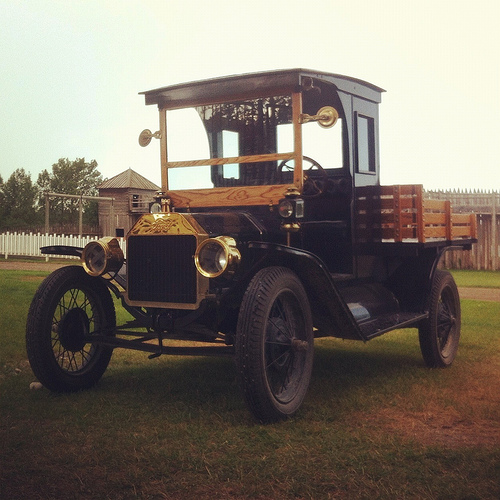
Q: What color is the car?
A: Black.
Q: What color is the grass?
A: Green.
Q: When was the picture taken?
A: Daytime.